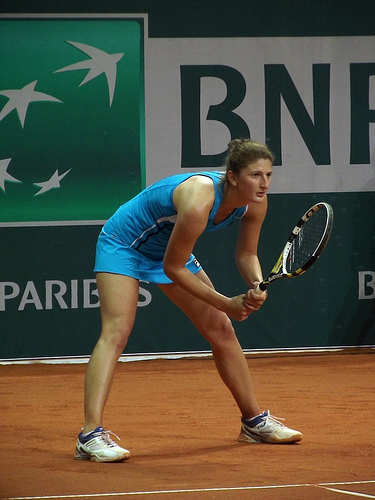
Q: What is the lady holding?
A: Tennis racket.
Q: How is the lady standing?
A: She is bending over.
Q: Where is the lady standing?
A: A tennis court.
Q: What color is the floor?
A: Brown.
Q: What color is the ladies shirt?
A: Blue, black and white.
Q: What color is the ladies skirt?
A: Blue.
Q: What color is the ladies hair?
A: Brown.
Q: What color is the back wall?
A: Green and white.